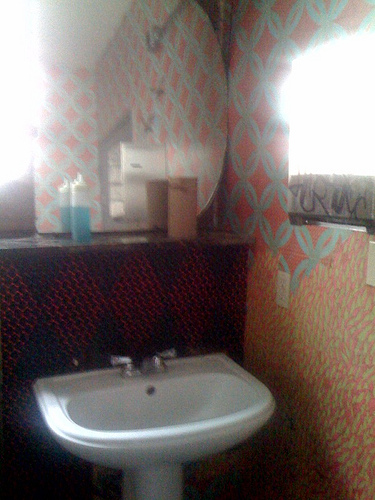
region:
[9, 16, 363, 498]
the bathroom sink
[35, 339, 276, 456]
the sink in the bathroom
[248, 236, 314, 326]
a electricty outlet in the bathroom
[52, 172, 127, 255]
a bottle of soup above the sink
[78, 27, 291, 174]
a mirror in the bathroom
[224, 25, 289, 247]
a bunch of cool designs on the side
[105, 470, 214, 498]
the base of the sink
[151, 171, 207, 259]
a empty toilet paper roll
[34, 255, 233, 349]
red diamonds on the wall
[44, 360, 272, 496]
A white pedestal sink in bathroom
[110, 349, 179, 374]
Two faucets on a pedestal sink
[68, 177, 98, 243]
A bottle of blue hand wash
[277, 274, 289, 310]
A white electrical socket on wall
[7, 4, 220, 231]
A large mirror in the toilet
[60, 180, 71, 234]
Reflection of a bottle of hand wash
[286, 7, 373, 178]
A very bright source of light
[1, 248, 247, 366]
Purple colored wall with flowers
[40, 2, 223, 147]
Reflection of wall in the mirror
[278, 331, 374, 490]
Multicolored wall in the toilet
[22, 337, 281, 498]
Sink is white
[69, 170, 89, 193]
Cap is white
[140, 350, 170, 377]
Faucet color silver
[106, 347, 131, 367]
Handle of sink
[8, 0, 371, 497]
Wall of bathroom is cover with decorated paper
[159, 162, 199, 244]
Tube of toilet paper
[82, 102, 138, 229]
Door is reflected in mirror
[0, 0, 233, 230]
Mirror is round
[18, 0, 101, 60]
Ceiling of bathroom is white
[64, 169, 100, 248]
White bottle containing blue liquid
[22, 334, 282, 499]
Sink on a bathroom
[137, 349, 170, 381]
Faucet of sink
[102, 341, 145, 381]
Left handle of sink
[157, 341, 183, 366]
Right handle of sink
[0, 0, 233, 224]
Mirror on top of sink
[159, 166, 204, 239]
Tube of toilet paper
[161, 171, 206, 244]
Tube is carboard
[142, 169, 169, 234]
Reflection on mirror of tube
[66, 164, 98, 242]
Bottle with white cap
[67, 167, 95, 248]
Bottle has blue liquid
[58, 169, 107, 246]
a bottle of blue liquid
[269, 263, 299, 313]
an off-white electrical outlet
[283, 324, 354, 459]
red and yellow wallpaper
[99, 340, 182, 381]
a stainless steel faucet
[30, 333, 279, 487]
a white porcelain sink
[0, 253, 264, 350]
a diamond patterned wallpaper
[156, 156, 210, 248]
a roll of brown paper towels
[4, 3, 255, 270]
a large mirror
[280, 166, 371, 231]
some black graffiti on wall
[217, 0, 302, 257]
a blue and red wall